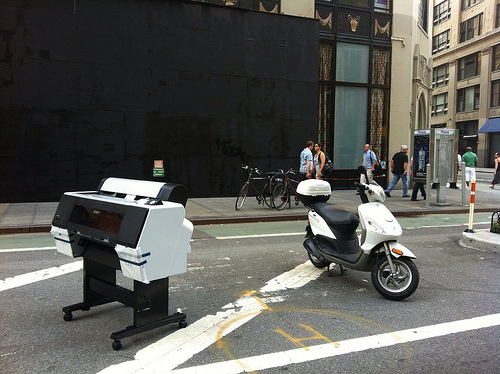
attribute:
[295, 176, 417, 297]
motorcycle — black, white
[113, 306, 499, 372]
line — white, on road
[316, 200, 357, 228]
seat — black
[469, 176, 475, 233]
pole — red, white, orange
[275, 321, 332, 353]
h — on road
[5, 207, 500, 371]
road — dry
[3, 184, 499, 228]
sidewalk — paved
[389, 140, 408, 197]
man — walking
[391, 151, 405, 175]
t-shirt — black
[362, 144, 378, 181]
man — bald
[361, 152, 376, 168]
shirt — blue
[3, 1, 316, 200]
wall — black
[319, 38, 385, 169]
window — tall, big, glass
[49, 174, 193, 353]
barbeque — big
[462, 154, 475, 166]
shirt — green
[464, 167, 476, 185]
pants — white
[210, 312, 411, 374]
circle — yellow